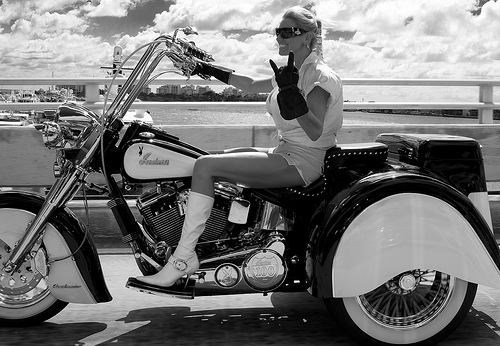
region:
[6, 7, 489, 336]
Black and white photograph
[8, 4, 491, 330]
Blond woman riding motorcycle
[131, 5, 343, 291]
Woman wearing white boots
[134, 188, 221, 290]
White high heeled boot with buckle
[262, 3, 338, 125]
Smiling woman wearing black sunglasses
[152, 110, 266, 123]
Body of water in background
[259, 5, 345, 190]
Woman wearing shorts and knotted shirt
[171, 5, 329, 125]
Woman wearing black gloves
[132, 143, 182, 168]
"Indian" logo on motorcycle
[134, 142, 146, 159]
"Playboy bunny" logo on motorcycle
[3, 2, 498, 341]
Black and white image of girl riding a vintage Indian motorcycle.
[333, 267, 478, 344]
Wire spoked rear motorcycle wheel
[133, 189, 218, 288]
Female, high-heeled, white leather boot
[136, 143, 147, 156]
Playboy brand bunny image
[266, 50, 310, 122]
Black riding glove flashing a hand gesture.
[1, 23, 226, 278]
Chrome chopper style front fork and handlebars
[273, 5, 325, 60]
Young, blond female wearing dark wrap-around sunglasses.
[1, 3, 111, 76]
Many puffy white clouds in sky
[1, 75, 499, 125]
Highway bridge spanning water with city in distance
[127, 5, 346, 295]
Smiling girl riding motorcycle in white shirt and boots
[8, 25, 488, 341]
a woman is sitting on the motorcycle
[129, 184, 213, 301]
white knee high boots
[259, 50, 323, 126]
black leather gloves on the woman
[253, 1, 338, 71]
The woman is wearing sunglasses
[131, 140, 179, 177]
A playboy bunny logo next to the Indian logo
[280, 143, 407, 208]
the black leather seat has metal studs on it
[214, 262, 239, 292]
the playboy bunny logo on the metal embellishment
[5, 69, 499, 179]
the median protecting drivers on the road from the water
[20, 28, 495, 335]
the motorcycle has long handlebars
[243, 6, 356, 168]
The woman is not wearing a helmet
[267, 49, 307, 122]
Black gloves in the photo.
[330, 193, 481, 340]
Wheel in the photo.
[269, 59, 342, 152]
White top in the photo.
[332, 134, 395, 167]
Black seat in the picture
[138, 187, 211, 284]
White boot in the photo.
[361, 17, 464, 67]
Cloudy skies in the photo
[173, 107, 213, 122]
Water body in the photo.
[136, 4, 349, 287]
A lady riding in a motor cycle.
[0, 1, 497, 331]
A motor cycle in the photo.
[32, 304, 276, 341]
Road with tarmac in the picture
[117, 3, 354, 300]
a hot biker babe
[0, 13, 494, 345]
woman on a three wheel cycle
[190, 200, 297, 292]
parts of the cycle covered with chrome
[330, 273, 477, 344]
white wall tire on the cycle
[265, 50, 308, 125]
gloved hand of biker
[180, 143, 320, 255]
left leg of the biker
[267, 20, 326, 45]
sun glasses on the cyclist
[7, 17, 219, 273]
chromed handle bars a steering shaft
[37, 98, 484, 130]
water behind the bridge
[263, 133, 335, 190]
shorts on the cyclist